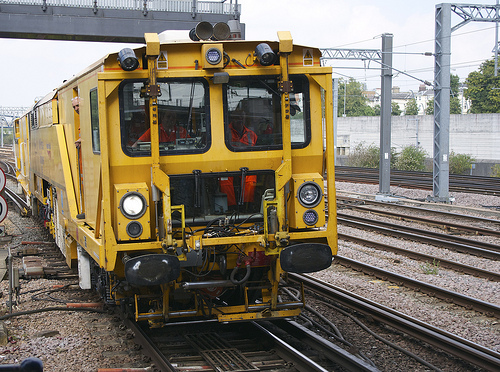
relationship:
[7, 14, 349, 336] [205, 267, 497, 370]
train on top of tracks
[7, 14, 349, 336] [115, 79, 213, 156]
train has window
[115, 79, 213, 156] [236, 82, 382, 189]
window has windows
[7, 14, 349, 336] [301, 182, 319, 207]
train has headlight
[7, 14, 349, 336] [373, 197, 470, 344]
train on top of tracks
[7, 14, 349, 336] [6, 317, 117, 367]
train on ground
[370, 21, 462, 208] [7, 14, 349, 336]
poles on train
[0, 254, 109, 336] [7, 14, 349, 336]
wire on train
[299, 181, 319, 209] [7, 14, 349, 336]
light on train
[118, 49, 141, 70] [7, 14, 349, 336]
headlight on train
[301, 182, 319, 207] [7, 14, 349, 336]
headlight on train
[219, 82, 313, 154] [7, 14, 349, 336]
window on train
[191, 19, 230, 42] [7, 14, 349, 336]
horn on train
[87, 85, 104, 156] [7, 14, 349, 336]
window on train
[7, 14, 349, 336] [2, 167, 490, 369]
train on tracks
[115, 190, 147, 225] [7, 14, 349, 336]
headlight on train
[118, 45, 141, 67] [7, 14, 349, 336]
spot lights on train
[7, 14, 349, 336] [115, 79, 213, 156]
train on window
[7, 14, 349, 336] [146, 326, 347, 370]
train on track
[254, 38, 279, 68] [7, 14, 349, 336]
spotlight on a train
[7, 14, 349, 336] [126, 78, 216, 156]
train with window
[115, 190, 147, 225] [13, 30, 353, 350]
headlight on a yellow train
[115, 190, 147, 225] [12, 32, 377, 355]
headlight on train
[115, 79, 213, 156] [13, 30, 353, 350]
window on a yellow train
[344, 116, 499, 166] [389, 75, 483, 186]
wall on far right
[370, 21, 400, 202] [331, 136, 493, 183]
poles built in yard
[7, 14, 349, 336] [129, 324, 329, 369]
train on track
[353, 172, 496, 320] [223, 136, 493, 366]
gravel in track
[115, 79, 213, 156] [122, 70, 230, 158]
window on train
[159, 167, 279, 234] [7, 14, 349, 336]
window on train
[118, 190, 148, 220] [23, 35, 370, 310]
light on train